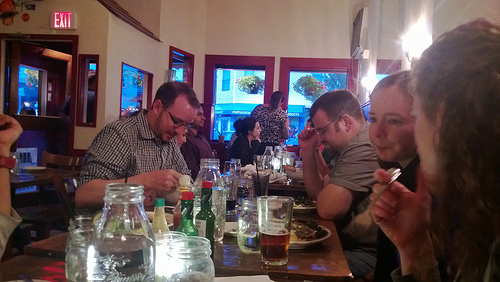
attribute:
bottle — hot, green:
[196, 179, 216, 260]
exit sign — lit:
[50, 11, 78, 30]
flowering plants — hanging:
[235, 76, 327, 102]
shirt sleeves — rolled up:
[73, 126, 194, 193]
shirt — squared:
[75, 107, 194, 217]